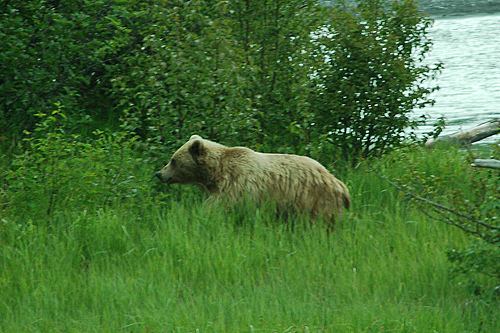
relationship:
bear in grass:
[154, 134, 353, 234] [104, 212, 352, 311]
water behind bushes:
[275, 26, 496, 148] [293, 17, 397, 129]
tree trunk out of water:
[470, 159, 496, 171] [455, 49, 497, 104]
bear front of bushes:
[148, 126, 359, 238] [152, 9, 380, 136]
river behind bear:
[290, 14, 498, 144] [156, 130, 355, 232]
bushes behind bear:
[2, 0, 447, 203] [156, 130, 355, 232]